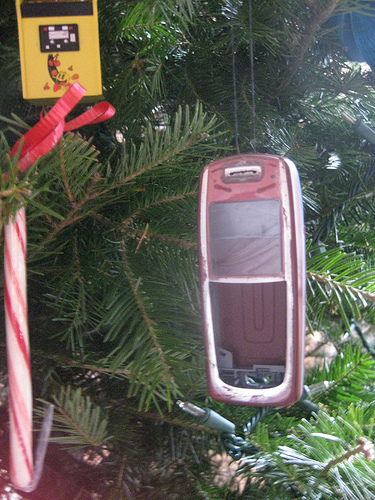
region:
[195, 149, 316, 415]
red cell phone in tree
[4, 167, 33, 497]
candy cane in tree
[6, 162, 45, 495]
red and white candy cane in tree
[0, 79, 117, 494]
candy cane with red ribbon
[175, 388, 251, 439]
white Christmas fairy light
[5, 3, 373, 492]
fresh pine Christmas tree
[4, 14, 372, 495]
green Evergreen tree with decorations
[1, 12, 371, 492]
this is an indoor Christmastime scene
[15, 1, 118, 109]
yellow object hanging in tree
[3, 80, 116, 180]
red ribbon bow in green tree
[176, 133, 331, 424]
a broken red phone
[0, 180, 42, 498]
a red and white peppermint stick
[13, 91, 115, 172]
a red ribbon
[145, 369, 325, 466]
a white Christmas light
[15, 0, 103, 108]
a yellow PAC-man ornament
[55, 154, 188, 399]
branches with green pine needles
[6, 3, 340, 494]
ornament on a Christmas tree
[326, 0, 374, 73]
a blue ornament from a tree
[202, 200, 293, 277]
a clear phone screen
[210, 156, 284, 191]
the phone's ear piece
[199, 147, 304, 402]
cell phone with small screen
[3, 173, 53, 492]
candy cane on a tree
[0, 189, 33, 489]
red and white candy cane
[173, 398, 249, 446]
a mini light on a tree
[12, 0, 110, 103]
electronic device on a tree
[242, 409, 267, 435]
twisted cord for mini lights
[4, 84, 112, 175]
red ribbon on a tree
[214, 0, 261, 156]
two strands holding up a phone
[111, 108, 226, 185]
a twig of a tree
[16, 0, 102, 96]
a yellow and black device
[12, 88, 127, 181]
red ribbon hanging in Christmas tree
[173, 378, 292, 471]
clear light in a Christmas tree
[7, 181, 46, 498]
red and white candy cane hanging in Christmas treet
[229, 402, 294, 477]
green wires to lights hanging in Christmas tree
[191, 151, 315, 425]
burgundy cell phone ornament in a Christmas tree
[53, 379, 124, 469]
green limb of evergreen Christmas tree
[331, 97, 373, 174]
clear light bulb in Christmas tree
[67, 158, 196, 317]
branches of pine tree decorated for Christmas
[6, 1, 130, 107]
Pac-man Christmas ornament in Christmas tree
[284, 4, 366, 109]
limbs of evergreen Christmas tree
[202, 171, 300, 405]
this is a toy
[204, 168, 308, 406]
the toy is maroon in color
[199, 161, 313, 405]
the toy is rectangle in shape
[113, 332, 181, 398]
these are leaflets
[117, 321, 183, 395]
the leaflets are green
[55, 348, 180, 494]
this are tree branches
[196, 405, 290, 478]
the is a rope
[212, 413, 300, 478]
the rope is green in color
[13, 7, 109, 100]
this is a yellow box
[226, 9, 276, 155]
these are ropes tied on a tree